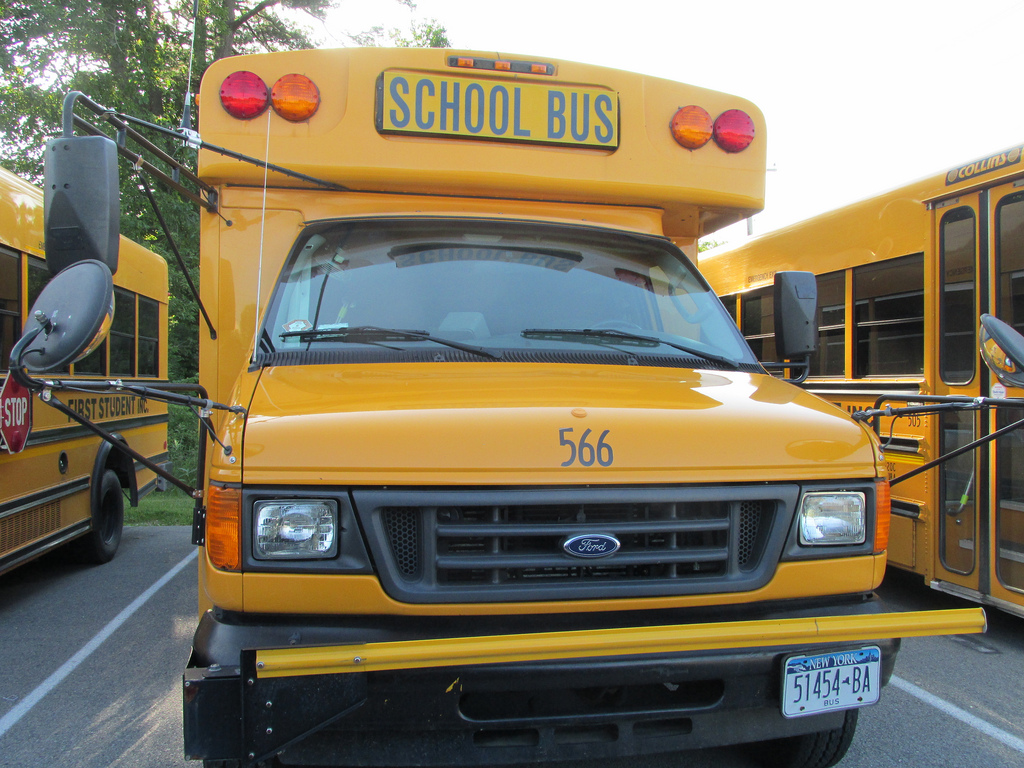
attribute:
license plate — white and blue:
[781, 644, 885, 716]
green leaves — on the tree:
[10, 5, 175, 94]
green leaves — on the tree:
[1, 3, 187, 77]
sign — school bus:
[373, 61, 624, 150]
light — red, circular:
[710, 109, 756, 153]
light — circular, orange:
[671, 98, 713, 153]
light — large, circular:
[271, 70, 326, 127]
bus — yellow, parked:
[170, 31, 1004, 758]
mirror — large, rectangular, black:
[38, 124, 129, 278]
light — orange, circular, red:
[714, 102, 754, 155]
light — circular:
[666, 102, 716, 146]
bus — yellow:
[688, 128, 1023, 634]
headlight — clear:
[249, 495, 343, 552]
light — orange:
[204, 478, 244, 561]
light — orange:
[872, 469, 892, 539]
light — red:
[710, 106, 756, 163]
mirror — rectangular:
[38, 117, 131, 297]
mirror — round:
[5, 253, 120, 388]